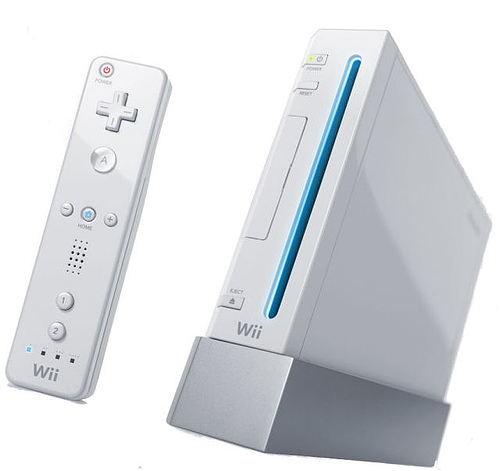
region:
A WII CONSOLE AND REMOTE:
[1, 1, 496, 464]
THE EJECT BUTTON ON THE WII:
[212, 286, 251, 313]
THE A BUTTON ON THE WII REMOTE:
[84, 144, 123, 176]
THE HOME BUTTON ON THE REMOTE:
[76, 201, 99, 228]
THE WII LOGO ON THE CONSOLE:
[222, 315, 276, 347]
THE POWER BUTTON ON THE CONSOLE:
[289, 47, 337, 74]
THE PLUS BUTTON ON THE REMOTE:
[101, 208, 125, 229]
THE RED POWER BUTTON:
[81, 56, 123, 86]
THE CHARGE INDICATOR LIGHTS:
[12, 343, 91, 383]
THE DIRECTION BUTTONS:
[91, 86, 143, 136]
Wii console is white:
[157, 10, 494, 460]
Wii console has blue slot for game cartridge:
[165, 26, 495, 466]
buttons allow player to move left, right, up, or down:
[75, 70, 165, 135]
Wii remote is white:
[5, 40, 175, 405]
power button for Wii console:
[270, 35, 335, 65]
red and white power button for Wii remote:
[85, 55, 120, 80]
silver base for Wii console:
[155, 330, 470, 465]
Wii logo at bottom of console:
[222, 310, 272, 345]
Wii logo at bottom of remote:
[20, 346, 80, 411]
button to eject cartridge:
[210, 278, 250, 318]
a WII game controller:
[0, 57, 170, 416]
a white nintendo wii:
[158, 39, 498, 464]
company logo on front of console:
[217, 316, 274, 344]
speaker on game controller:
[50, 231, 100, 275]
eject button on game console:
[203, 283, 253, 313]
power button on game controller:
[91, 59, 119, 84]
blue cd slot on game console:
[259, 53, 369, 318]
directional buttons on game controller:
[93, 91, 143, 134]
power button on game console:
[283, 49, 337, 77]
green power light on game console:
[301, 44, 315, 67]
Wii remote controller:
[0, 20, 168, 466]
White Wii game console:
[165, 2, 455, 467]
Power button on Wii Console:
[295, 41, 335, 67]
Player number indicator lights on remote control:
[15, 340, 85, 365]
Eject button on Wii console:
[210, 290, 250, 316]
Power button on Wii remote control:
[90, 55, 120, 85]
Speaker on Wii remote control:
[52, 230, 97, 277]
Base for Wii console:
[160, 325, 435, 467]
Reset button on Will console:
[280, 71, 325, 96]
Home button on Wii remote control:
[75, 205, 98, 228]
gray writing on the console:
[232, 318, 268, 340]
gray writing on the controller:
[27, 360, 63, 383]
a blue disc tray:
[259, 50, 366, 323]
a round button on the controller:
[53, 290, 79, 313]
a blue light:
[24, 341, 34, 356]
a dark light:
[37, 345, 45, 357]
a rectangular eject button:
[213, 285, 248, 314]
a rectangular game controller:
[2, 50, 174, 400]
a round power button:
[96, 58, 117, 82]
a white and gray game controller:
[150, 15, 499, 470]